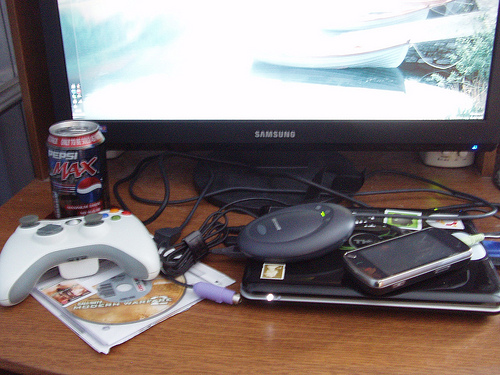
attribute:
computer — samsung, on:
[33, 0, 498, 159]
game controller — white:
[0, 206, 160, 308]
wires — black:
[110, 153, 499, 308]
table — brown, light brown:
[2, 136, 499, 374]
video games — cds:
[27, 231, 240, 359]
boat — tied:
[227, 2, 437, 70]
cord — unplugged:
[116, 152, 218, 249]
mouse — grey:
[230, 198, 357, 265]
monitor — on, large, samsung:
[33, 0, 498, 151]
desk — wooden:
[2, 139, 499, 374]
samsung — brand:
[253, 127, 301, 141]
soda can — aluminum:
[41, 117, 112, 218]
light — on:
[468, 143, 479, 152]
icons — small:
[68, 81, 87, 119]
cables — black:
[108, 148, 498, 274]